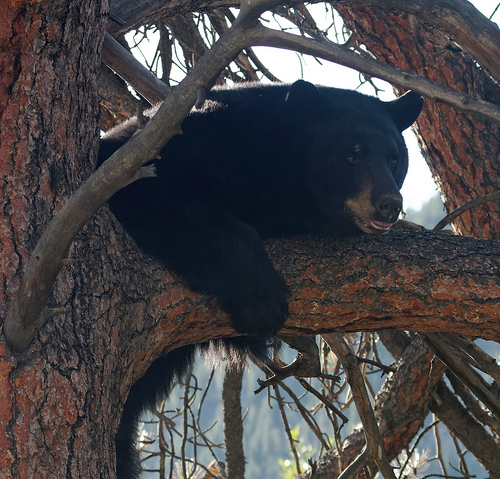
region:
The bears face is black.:
[284, 81, 448, 238]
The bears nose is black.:
[374, 187, 406, 220]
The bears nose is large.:
[370, 190, 407, 220]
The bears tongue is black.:
[371, 214, 396, 230]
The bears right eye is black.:
[348, 147, 360, 168]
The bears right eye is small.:
[346, 145, 361, 165]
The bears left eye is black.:
[388, 153, 401, 168]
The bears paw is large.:
[227, 271, 303, 340]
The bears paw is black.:
[210, 281, 300, 340]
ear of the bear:
[390, 73, 443, 131]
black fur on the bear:
[235, 81, 343, 165]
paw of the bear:
[198, 226, 318, 354]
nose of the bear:
[346, 173, 426, 237]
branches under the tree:
[178, 354, 461, 477]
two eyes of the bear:
[325, 138, 414, 175]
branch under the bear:
[308, 244, 443, 318]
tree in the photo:
[1, 29, 118, 164]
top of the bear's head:
[324, 93, 396, 151]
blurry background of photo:
[228, 396, 285, 459]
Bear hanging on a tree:
[83, 78, 423, 476]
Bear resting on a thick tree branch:
[81, 80, 422, 477]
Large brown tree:
[0, 0, 499, 477]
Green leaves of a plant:
[275, 421, 336, 477]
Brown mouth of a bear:
[341, 177, 404, 238]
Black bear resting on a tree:
[93, 78, 426, 477]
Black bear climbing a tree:
[89, 78, 425, 477]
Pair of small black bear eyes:
[344, 145, 401, 172]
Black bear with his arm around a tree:
[83, 74, 424, 477]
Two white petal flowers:
[391, 443, 434, 476]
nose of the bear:
[362, 181, 416, 216]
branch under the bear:
[262, 228, 481, 347]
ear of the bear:
[273, 70, 345, 125]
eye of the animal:
[323, 132, 380, 184]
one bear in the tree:
[73, 76, 448, 351]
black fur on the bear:
[188, 99, 308, 182]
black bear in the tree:
[116, 81, 444, 304]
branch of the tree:
[256, 373, 305, 461]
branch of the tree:
[308, 385, 363, 446]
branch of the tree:
[142, 390, 193, 459]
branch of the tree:
[406, 422, 439, 468]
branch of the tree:
[347, 342, 399, 396]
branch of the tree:
[281, 6, 333, 69]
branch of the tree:
[93, 50, 188, 96]